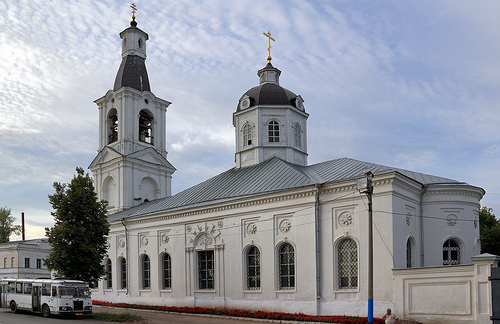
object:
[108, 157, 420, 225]
church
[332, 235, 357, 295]
window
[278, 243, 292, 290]
window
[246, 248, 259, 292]
window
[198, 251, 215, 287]
window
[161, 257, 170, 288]
window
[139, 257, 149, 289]
window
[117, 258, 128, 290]
window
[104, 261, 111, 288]
window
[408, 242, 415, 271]
window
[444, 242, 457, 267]
window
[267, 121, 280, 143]
window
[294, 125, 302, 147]
window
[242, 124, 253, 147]
window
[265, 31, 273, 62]
cross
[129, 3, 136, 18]
cross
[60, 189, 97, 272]
tree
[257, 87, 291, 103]
roof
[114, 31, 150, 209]
belltower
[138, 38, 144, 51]
window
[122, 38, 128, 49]
window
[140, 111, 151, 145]
window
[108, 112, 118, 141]
window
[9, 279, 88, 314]
bus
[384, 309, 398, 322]
man